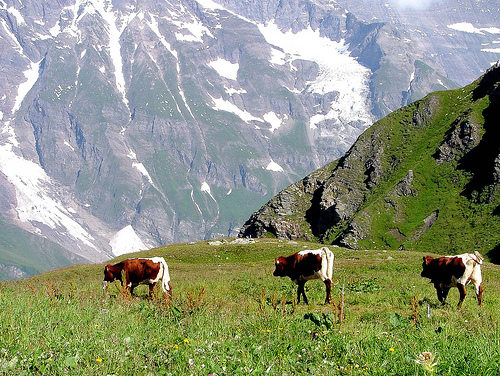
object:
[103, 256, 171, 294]
cow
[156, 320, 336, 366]
grass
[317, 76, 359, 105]
snow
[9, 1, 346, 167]
mountain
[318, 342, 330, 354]
flowers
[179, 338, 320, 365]
weeds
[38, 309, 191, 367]
grass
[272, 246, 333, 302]
cow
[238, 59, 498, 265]
hill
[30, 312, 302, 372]
field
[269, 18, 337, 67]
snow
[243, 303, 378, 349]
weeds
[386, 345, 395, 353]
flowers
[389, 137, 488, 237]
greenery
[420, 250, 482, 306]
cow